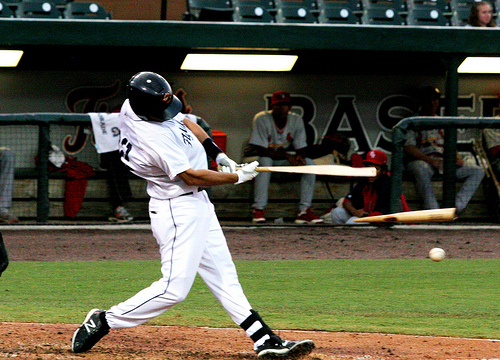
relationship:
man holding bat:
[67, 70, 317, 360] [247, 160, 383, 182]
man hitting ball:
[17, 63, 345, 358] [403, 225, 459, 277]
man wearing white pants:
[67, 70, 317, 360] [122, 192, 249, 314]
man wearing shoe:
[67, 70, 317, 360] [253, 329, 323, 358]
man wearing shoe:
[67, 70, 317, 360] [64, 308, 111, 353]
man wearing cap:
[249, 89, 317, 226] [269, 87, 294, 107]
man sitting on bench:
[221, 66, 382, 276] [54, 115, 486, 244]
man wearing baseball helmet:
[249, 89, 317, 226] [127, 71, 183, 121]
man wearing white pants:
[67, 70, 317, 360] [103, 189, 250, 329]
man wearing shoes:
[67, 70, 317, 360] [51, 307, 156, 358]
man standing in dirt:
[67, 70, 317, 360] [0, 319, 496, 360]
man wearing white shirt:
[249, 89, 317, 226] [247, 108, 309, 152]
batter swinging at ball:
[109, 63, 322, 355] [428, 247, 446, 262]